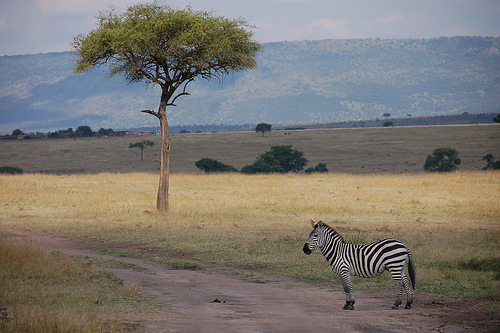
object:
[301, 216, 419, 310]
zebra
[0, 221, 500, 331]
road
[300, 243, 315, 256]
snout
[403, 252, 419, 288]
tail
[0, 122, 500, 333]
plains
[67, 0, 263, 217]
tree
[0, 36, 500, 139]
hill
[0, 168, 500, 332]
field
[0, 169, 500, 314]
grass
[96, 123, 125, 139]
house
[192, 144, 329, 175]
bushes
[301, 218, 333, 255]
head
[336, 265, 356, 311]
legs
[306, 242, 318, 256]
mouth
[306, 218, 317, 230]
ears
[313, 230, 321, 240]
eye